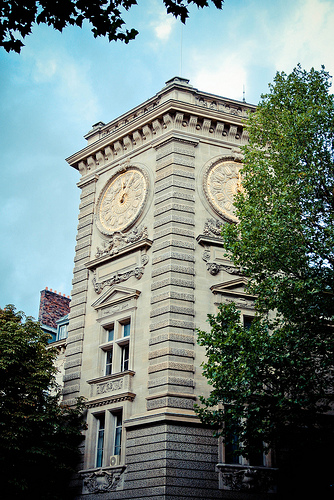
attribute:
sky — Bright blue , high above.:
[0, 4, 310, 288]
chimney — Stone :
[40, 284, 72, 324]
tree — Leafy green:
[202, 63, 322, 491]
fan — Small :
[109, 451, 122, 464]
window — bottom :
[89, 414, 111, 463]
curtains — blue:
[93, 425, 107, 464]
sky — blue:
[0, 20, 275, 78]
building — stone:
[59, 75, 278, 498]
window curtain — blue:
[96, 424, 122, 469]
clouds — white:
[30, 50, 101, 121]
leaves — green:
[239, 329, 318, 412]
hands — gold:
[119, 171, 135, 201]